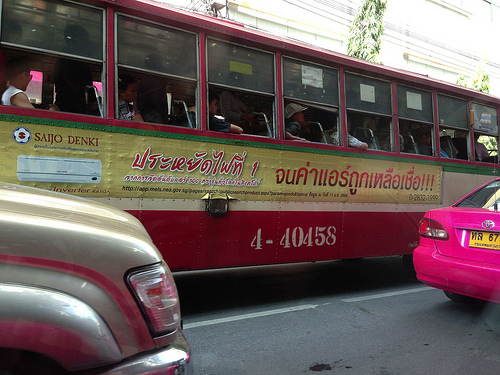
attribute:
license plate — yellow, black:
[467, 228, 499, 248]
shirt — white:
[1, 84, 26, 106]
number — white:
[249, 227, 264, 251]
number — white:
[278, 225, 291, 249]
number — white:
[301, 224, 314, 246]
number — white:
[312, 224, 325, 245]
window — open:
[2, 0, 110, 117]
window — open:
[113, 11, 201, 129]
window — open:
[205, 36, 279, 138]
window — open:
[281, 55, 344, 147]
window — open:
[342, 70, 392, 150]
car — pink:
[411, 177, 484, 303]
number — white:
[289, 224, 303, 247]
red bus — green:
[0, 0, 499, 275]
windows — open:
[2, 5, 204, 127]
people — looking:
[7, 18, 93, 109]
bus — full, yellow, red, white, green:
[0, 0, 489, 267]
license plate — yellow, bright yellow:
[466, 227, 499, 254]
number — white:
[247, 220, 347, 255]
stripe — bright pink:
[122, 171, 261, 187]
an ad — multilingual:
[25, 129, 439, 204]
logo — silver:
[10, 156, 104, 188]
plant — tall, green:
[353, 3, 388, 67]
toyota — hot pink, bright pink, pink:
[412, 176, 499, 297]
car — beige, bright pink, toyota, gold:
[1, 172, 199, 368]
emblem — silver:
[480, 215, 496, 232]